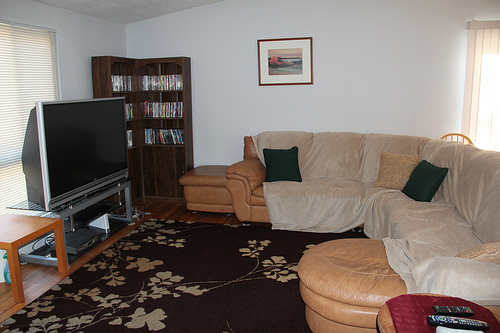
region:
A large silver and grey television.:
[18, 94, 138, 209]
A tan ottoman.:
[180, 155, 239, 212]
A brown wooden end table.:
[1, 212, 73, 302]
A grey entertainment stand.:
[9, 179, 135, 266]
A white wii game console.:
[89, 213, 114, 235]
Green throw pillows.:
[262, 147, 449, 204]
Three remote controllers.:
[429, 302, 491, 332]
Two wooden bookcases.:
[92, 55, 190, 200]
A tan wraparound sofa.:
[229, 134, 499, 331]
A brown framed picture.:
[255, 36, 315, 86]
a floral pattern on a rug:
[81, 260, 168, 332]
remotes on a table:
[426, 301, 488, 331]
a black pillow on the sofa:
[254, 135, 314, 189]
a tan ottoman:
[304, 232, 379, 331]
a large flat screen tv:
[31, 102, 133, 198]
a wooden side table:
[3, 209, 65, 286]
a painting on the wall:
[251, 25, 321, 91]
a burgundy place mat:
[388, 299, 423, 331]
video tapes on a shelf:
[141, 74, 185, 91]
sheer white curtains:
[470, 31, 487, 137]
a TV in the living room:
[21, 97, 141, 275]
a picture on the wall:
[253, 37, 313, 87]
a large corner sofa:
[230, 131, 498, 316]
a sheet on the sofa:
[252, 126, 499, 302]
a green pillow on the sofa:
[259, 144, 307, 184]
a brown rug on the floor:
[1, 211, 410, 328]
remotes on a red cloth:
[425, 302, 489, 330]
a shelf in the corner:
[87, 54, 196, 206]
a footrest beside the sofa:
[180, 155, 240, 215]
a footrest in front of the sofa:
[295, 232, 420, 331]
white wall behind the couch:
[323, 13, 446, 123]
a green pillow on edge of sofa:
[258, 142, 311, 187]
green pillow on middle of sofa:
[409, 156, 453, 211]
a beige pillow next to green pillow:
[378, 145, 415, 194]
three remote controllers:
[420, 294, 490, 331]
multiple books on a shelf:
[106, 68, 188, 152]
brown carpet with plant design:
[123, 225, 283, 327]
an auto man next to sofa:
[184, 159, 242, 218]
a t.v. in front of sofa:
[31, 92, 144, 208]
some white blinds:
[1, 22, 58, 216]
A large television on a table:
[21, 95, 123, 210]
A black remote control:
[430, 303, 474, 315]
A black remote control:
[428, 312, 490, 329]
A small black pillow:
[262, 144, 302, 181]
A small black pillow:
[401, 160, 448, 202]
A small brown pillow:
[375, 150, 422, 187]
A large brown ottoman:
[297, 237, 409, 332]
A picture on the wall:
[257, 35, 314, 87]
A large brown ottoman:
[178, 163, 233, 213]